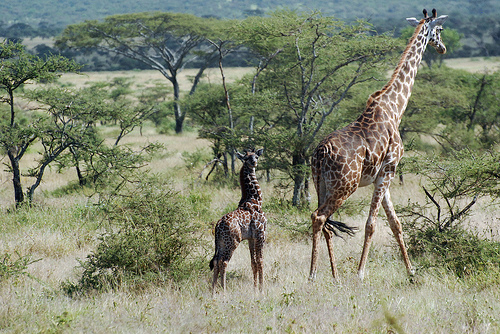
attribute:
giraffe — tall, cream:
[305, 7, 447, 291]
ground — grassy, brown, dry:
[2, 63, 499, 334]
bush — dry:
[88, 180, 199, 288]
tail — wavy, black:
[315, 148, 361, 239]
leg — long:
[356, 172, 396, 274]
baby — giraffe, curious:
[207, 147, 268, 294]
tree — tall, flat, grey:
[55, 12, 258, 134]